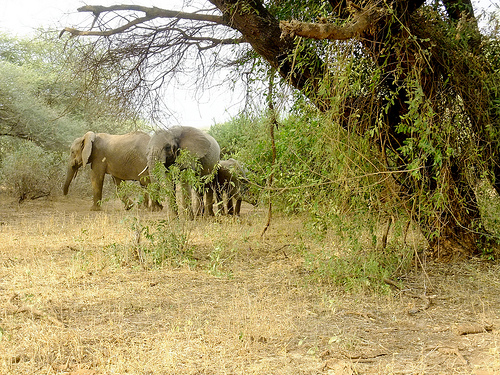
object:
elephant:
[143, 124, 220, 214]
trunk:
[146, 152, 158, 211]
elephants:
[59, 124, 243, 220]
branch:
[220, 0, 389, 135]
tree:
[57, 1, 500, 250]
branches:
[60, 1, 373, 121]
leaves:
[237, 27, 499, 241]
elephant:
[200, 160, 262, 208]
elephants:
[63, 126, 224, 220]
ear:
[81, 133, 98, 167]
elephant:
[63, 131, 151, 210]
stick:
[111, 207, 234, 267]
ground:
[2, 192, 499, 374]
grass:
[0, 197, 499, 370]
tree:
[2, 27, 129, 202]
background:
[1, 3, 499, 186]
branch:
[275, 11, 366, 41]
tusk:
[135, 165, 148, 177]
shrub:
[114, 151, 199, 223]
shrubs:
[0, 109, 400, 287]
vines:
[266, 20, 478, 289]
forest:
[0, 1, 495, 374]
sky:
[4, 6, 44, 29]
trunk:
[205, 187, 215, 216]